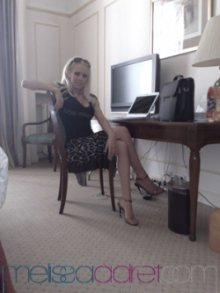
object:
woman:
[22, 56, 165, 226]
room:
[0, 0, 220, 293]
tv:
[110, 54, 161, 112]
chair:
[47, 95, 116, 212]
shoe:
[117, 198, 139, 227]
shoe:
[134, 178, 164, 200]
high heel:
[118, 204, 121, 219]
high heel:
[134, 182, 142, 195]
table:
[107, 114, 220, 240]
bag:
[159, 72, 194, 123]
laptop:
[115, 93, 159, 120]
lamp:
[191, 16, 219, 120]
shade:
[192, 14, 219, 68]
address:
[1, 263, 219, 288]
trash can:
[166, 174, 191, 235]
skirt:
[64, 129, 110, 176]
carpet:
[0, 162, 219, 293]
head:
[68, 57, 91, 91]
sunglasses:
[69, 57, 91, 66]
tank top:
[51, 83, 97, 139]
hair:
[61, 56, 92, 105]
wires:
[134, 137, 218, 209]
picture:
[150, 0, 214, 60]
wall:
[71, 0, 220, 206]